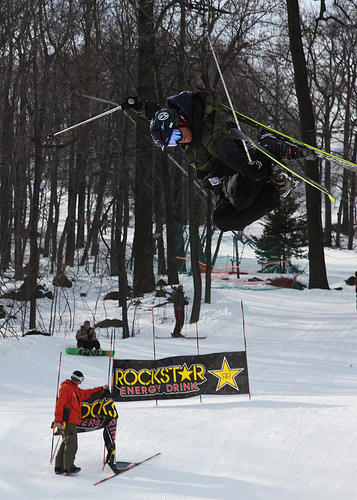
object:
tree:
[248, 193, 306, 278]